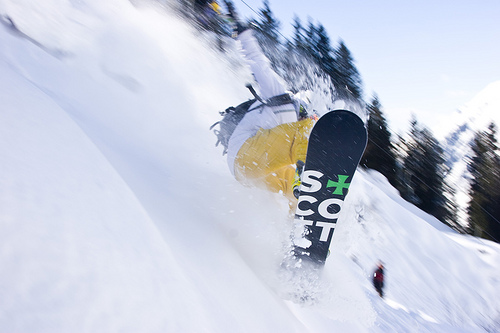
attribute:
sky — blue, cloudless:
[275, 6, 498, 149]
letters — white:
[294, 160, 326, 195]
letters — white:
[293, 192, 322, 219]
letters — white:
[287, 216, 314, 251]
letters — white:
[320, 197, 345, 219]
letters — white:
[316, 218, 345, 246]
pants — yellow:
[233, 115, 317, 220]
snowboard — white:
[282, 104, 372, 266]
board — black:
[0, 2, 500, 332]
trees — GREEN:
[242, 23, 497, 235]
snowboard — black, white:
[245, 98, 401, 307]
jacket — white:
[225, 32, 296, 170]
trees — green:
[463, 120, 498, 244]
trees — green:
[393, 124, 459, 224]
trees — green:
[357, 90, 394, 185]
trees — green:
[325, 37, 365, 110]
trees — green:
[314, 20, 331, 65]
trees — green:
[303, 16, 315, 73]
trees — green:
[288, 12, 306, 48]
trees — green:
[247, 0, 277, 42]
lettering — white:
[299, 164, 315, 249]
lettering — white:
[317, 195, 342, 239]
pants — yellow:
[221, 113, 299, 185]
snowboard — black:
[287, 103, 369, 283]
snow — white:
[57, 140, 178, 260]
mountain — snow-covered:
[0, 0, 498, 332]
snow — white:
[0, 2, 222, 324]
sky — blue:
[353, 25, 495, 168]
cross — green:
[327, 172, 354, 196]